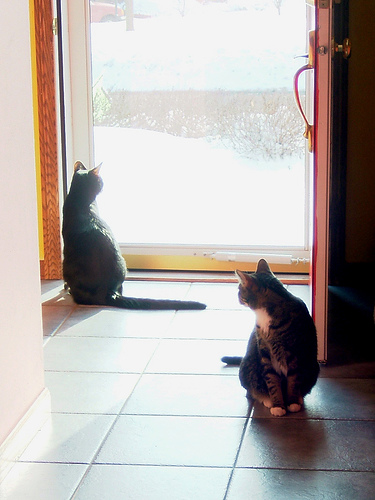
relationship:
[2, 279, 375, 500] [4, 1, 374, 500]
floor inside house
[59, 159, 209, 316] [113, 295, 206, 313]
cat has tail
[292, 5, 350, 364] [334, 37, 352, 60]
door has handle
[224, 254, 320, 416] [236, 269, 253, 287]
cat has ear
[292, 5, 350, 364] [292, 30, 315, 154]
door has handle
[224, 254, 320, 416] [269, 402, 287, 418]
cat has paw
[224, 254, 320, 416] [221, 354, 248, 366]
cat has tail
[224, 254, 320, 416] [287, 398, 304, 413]
cat has paw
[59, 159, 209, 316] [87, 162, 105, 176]
cat has ear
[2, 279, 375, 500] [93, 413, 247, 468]
floor has tile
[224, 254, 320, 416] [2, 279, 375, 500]
cat on top of floor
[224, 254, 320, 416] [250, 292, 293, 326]
cat has neck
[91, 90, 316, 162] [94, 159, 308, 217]
plants full of snow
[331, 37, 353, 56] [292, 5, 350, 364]
handle in door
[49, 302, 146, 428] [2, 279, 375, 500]
light shining on floor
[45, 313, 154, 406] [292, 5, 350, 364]
light shining through door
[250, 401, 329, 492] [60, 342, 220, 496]
shadow on floor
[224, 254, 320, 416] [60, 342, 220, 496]
cat on floor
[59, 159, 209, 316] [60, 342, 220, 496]
cat on floor